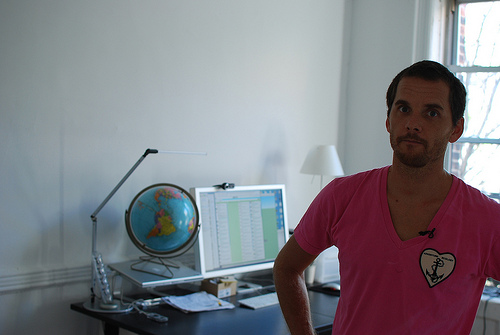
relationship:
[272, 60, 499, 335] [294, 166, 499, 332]
man wearing shirt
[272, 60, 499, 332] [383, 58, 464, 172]
man has hair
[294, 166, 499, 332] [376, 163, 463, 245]
shirt has vee neck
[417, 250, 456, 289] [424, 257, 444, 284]
heart has anchor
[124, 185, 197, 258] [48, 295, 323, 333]
globe on desk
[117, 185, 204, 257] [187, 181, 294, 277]
globe next monitor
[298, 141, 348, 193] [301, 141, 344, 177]
lamp had shade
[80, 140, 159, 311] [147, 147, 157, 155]
tall lamp has led bulbs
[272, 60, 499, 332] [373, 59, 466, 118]
man has hair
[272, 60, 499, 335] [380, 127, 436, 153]
man has moustache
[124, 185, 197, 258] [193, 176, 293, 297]
globe next monitor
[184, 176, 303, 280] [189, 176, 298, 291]
frame on monitor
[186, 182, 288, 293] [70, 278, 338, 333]
monitor on desk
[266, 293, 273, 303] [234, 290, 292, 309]
key on keyboard